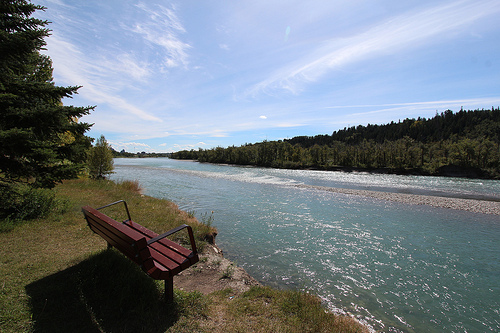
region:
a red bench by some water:
[71, 197, 209, 307]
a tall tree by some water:
[0, 3, 82, 228]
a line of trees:
[179, 134, 496, 164]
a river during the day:
[239, 183, 491, 273]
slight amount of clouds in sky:
[60, 5, 485, 97]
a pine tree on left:
[3, 2, 78, 211]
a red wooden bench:
[84, 186, 196, 308]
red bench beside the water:
[102, 155, 496, 332]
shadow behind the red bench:
[22, 251, 179, 332]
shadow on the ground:
[1, 176, 376, 331]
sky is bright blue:
[2, 0, 495, 152]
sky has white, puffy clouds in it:
[2, 0, 498, 153]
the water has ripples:
[92, 155, 498, 332]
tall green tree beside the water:
[0, 1, 97, 191]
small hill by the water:
[170, 106, 498, 181]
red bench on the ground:
[72, 196, 199, 304]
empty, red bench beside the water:
[78, 196, 199, 296]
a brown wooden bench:
[76, 193, 226, 316]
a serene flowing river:
[103, 150, 498, 330]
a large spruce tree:
[1, 0, 96, 191]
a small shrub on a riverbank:
[197, 209, 217, 236]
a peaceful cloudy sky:
[44, 5, 494, 139]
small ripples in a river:
[278, 208, 435, 332]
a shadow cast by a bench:
[20, 247, 178, 331]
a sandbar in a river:
[281, 173, 498, 215]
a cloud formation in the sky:
[133, 2, 193, 77]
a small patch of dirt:
[179, 243, 258, 329]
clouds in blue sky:
[27, 2, 499, 154]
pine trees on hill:
[206, 105, 496, 167]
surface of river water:
[110, 156, 498, 328]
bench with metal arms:
[80, 199, 196, 279]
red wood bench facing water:
[82, 159, 349, 279]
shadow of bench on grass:
[27, 247, 174, 331]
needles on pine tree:
[0, 2, 94, 190]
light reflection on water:
[253, 195, 405, 309]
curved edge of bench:
[138, 237, 196, 280]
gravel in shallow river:
[301, 181, 498, 211]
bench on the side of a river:
[77, 191, 207, 311]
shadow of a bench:
[21, 245, 183, 332]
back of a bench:
[79, 204, 154, 269]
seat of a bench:
[111, 212, 196, 281]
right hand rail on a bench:
[143, 220, 202, 260]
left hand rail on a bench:
[95, 199, 130, 219]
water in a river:
[97, 146, 495, 329]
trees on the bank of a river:
[164, 105, 499, 188]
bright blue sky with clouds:
[26, 0, 493, 161]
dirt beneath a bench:
[153, 250, 245, 302]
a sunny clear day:
[2, 0, 499, 330]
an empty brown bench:
[79, 193, 197, 313]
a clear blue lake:
[110, 135, 496, 330]